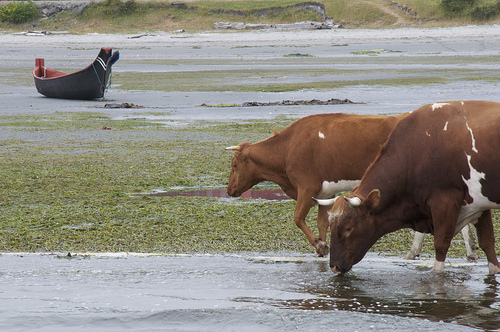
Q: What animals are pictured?
A: Cows.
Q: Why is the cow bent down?
A: To drink.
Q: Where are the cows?
A: In the water.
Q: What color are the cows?
A: Brown and white.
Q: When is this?
A: Daytime.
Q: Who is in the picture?
A: No one is in the picture.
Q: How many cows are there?
A: Two.